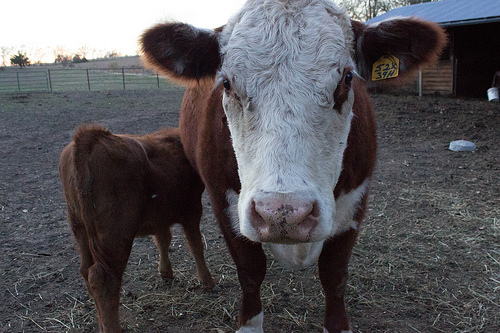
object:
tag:
[371, 52, 400, 82]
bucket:
[486, 87, 500, 103]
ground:
[0, 89, 500, 333]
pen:
[0, 91, 499, 331]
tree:
[10, 50, 30, 69]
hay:
[0, 91, 500, 332]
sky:
[0, 0, 246, 68]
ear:
[363, 13, 451, 88]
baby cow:
[58, 121, 225, 332]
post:
[418, 69, 423, 97]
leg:
[181, 216, 223, 293]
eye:
[341, 71, 354, 88]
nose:
[245, 190, 324, 245]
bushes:
[9, 52, 31, 68]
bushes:
[61, 56, 73, 65]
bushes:
[70, 53, 81, 65]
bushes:
[82, 55, 88, 62]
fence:
[0, 67, 174, 90]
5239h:
[374, 62, 398, 80]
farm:
[0, 0, 500, 333]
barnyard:
[0, 0, 500, 333]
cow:
[135, 0, 449, 333]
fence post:
[85, 67, 90, 91]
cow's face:
[213, 0, 359, 245]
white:
[218, 0, 363, 244]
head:
[134, 0, 450, 245]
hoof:
[234, 318, 267, 333]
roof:
[362, 0, 500, 29]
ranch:
[0, 0, 499, 333]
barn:
[361, 0, 500, 101]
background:
[0, 0, 247, 70]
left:
[0, 0, 13, 333]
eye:
[222, 78, 232, 91]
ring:
[333, 66, 356, 116]